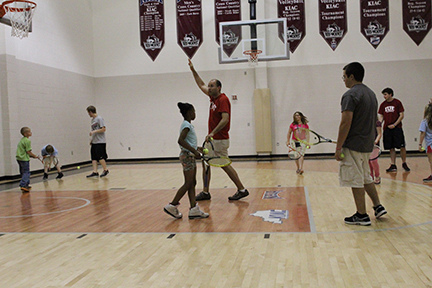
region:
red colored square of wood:
[1, 188, 311, 233]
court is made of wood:
[0, 157, 430, 285]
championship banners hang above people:
[137, 1, 430, 60]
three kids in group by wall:
[13, 103, 111, 192]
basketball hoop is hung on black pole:
[220, 3, 289, 67]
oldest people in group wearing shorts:
[83, 50, 409, 220]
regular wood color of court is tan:
[2, 157, 430, 287]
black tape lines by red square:
[0, 232, 279, 247]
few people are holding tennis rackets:
[183, 54, 392, 226]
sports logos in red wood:
[252, 188, 291, 228]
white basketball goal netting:
[4, 3, 41, 41]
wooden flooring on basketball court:
[182, 238, 317, 286]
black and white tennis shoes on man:
[330, 199, 391, 232]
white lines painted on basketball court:
[34, 193, 111, 225]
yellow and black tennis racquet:
[286, 122, 336, 153]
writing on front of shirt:
[379, 104, 398, 114]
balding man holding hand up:
[182, 59, 255, 207]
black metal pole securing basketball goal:
[245, 2, 262, 47]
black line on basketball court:
[161, 228, 178, 247]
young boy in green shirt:
[10, 115, 40, 194]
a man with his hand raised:
[182, 46, 252, 208]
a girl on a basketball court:
[162, 97, 208, 223]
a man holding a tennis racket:
[285, 59, 386, 226]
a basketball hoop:
[212, 4, 295, 76]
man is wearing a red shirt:
[203, 88, 235, 147]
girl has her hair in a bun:
[176, 98, 198, 123]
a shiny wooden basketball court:
[4, 143, 431, 284]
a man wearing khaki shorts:
[336, 142, 377, 196]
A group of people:
[8, 50, 428, 230]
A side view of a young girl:
[157, 93, 213, 228]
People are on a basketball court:
[4, 46, 427, 244]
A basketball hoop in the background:
[211, 11, 302, 72]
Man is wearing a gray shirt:
[326, 82, 384, 163]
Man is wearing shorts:
[331, 144, 392, 232]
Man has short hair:
[335, 51, 376, 92]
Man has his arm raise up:
[183, 48, 251, 203]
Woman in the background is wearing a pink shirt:
[278, 105, 314, 178]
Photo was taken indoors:
[2, 3, 430, 286]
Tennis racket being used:
[293, 124, 339, 146]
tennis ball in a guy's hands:
[335, 150, 345, 160]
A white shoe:
[164, 202, 183, 221]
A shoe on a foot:
[187, 201, 208, 218]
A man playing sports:
[84, 103, 109, 177]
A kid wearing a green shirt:
[14, 123, 40, 190]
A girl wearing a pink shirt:
[288, 110, 311, 176]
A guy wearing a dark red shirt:
[378, 85, 410, 172]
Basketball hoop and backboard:
[217, 18, 288, 71]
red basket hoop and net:
[1, 0, 36, 38]